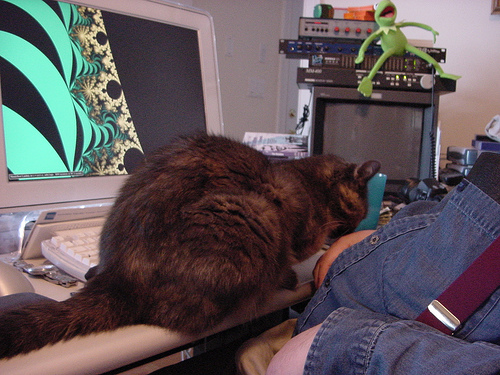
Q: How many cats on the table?
A: One.